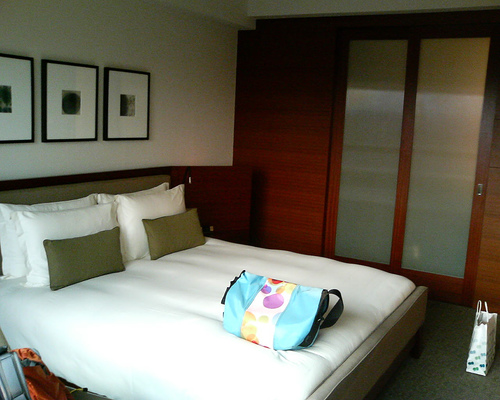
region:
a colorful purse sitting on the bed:
[221, 270, 341, 346]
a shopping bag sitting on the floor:
[463, 301, 498, 376]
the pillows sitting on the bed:
[0, 180, 206, 295]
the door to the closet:
[331, 26, 492, 286]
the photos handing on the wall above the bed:
[0, 50, 150, 146]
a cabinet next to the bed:
[167, 161, 257, 236]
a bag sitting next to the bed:
[2, 344, 70, 399]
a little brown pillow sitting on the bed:
[38, 225, 125, 285]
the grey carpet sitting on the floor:
[381, 289, 498, 397]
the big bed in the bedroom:
[6, 167, 422, 398]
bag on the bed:
[237, 274, 318, 344]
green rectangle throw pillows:
[49, 210, 204, 275]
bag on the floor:
[460, 289, 499, 392]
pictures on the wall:
[4, 48, 167, 145]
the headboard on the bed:
[9, 176, 203, 253]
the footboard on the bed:
[296, 261, 444, 396]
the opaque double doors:
[347, 35, 475, 310]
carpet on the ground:
[394, 296, 487, 389]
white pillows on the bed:
[4, 195, 229, 265]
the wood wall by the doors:
[237, 29, 494, 277]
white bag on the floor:
[456, 293, 493, 383]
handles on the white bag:
[471, 287, 488, 320]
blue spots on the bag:
[464, 346, 484, 378]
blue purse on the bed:
[206, 259, 353, 353]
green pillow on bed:
[143, 212, 204, 248]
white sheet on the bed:
[74, 290, 200, 360]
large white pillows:
[18, 188, 146, 222]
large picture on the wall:
[98, 53, 185, 152]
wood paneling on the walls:
[268, 71, 323, 179]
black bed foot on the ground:
[403, 327, 433, 353]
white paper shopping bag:
[464, 296, 496, 381]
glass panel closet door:
[321, 31, 494, 271]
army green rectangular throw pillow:
[42, 222, 127, 292]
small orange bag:
[18, 346, 68, 398]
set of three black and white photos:
[1, 56, 150, 144]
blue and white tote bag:
[218, 271, 341, 354]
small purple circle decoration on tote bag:
[262, 293, 284, 310]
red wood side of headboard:
[175, 165, 257, 233]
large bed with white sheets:
[3, 165, 428, 399]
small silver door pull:
[477, 179, 484, 199]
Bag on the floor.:
[463, 298, 495, 380]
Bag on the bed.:
[215, 265, 347, 358]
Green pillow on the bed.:
[137, 205, 211, 263]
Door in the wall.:
[328, 45, 491, 302]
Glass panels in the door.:
[335, 49, 494, 289]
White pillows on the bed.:
[2, 200, 121, 279]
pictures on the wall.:
[0, 51, 159, 147]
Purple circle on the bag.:
[260, 289, 285, 310]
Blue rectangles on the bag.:
[464, 333, 496, 382]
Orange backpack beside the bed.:
[0, 345, 70, 398]